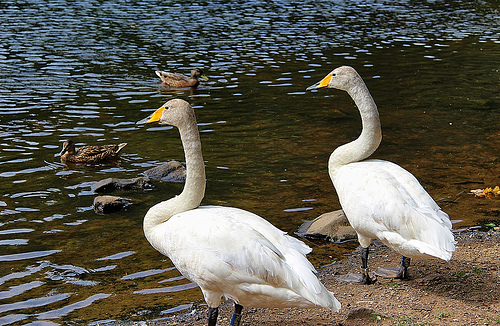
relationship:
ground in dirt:
[296, 238, 499, 324] [332, 273, 392, 323]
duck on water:
[58, 138, 128, 164] [48, 28, 136, 107]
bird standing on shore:
[305, 65, 456, 286] [315, 260, 497, 323]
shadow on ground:
[394, 260, 490, 308] [359, 290, 427, 322]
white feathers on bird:
[173, 215, 290, 287] [134, 97, 343, 326]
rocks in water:
[81, 167, 146, 204] [25, 40, 121, 250]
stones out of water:
[36, 16, 107, 119] [107, 15, 468, 166]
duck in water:
[152, 66, 211, 94] [199, 15, 485, 59]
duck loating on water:
[155, 67, 209, 87] [7, 7, 494, 317]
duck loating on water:
[57, 139, 118, 169] [7, 7, 494, 317]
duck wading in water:
[149, 49, 251, 103] [192, 27, 332, 81]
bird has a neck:
[134, 99, 341, 324] [145, 125, 206, 225]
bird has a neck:
[306, 63, 457, 285] [324, 87, 383, 166]